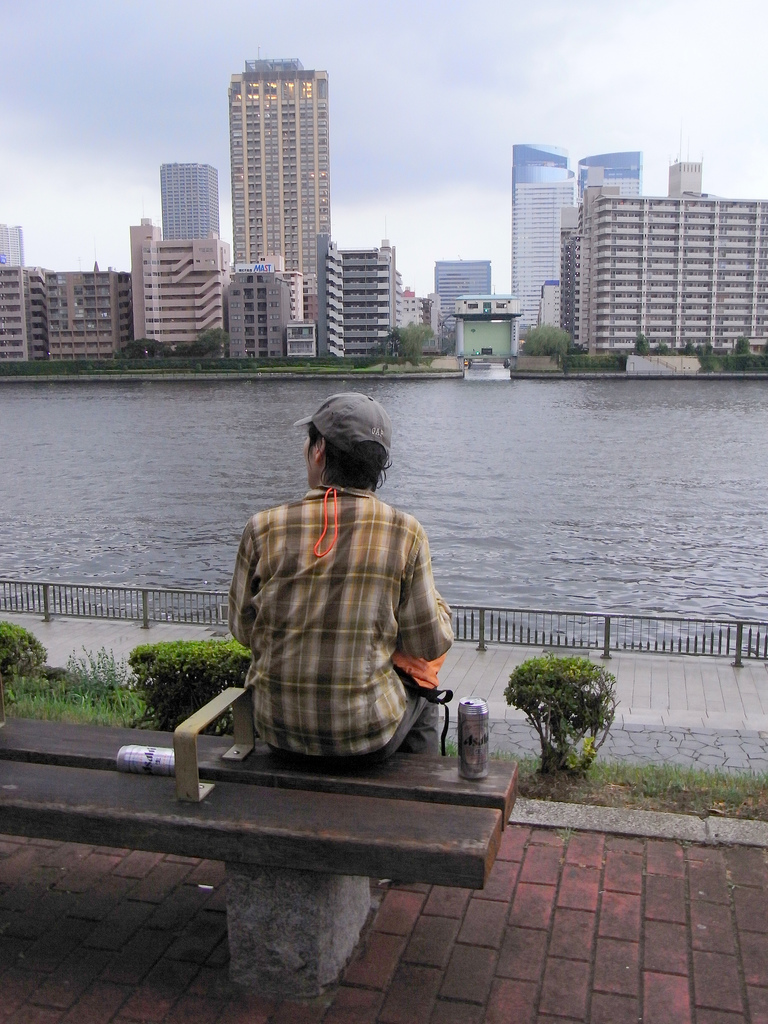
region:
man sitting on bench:
[201, 377, 443, 768]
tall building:
[132, 41, 364, 365]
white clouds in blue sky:
[66, 55, 108, 99]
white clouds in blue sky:
[123, 61, 203, 130]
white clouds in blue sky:
[381, 71, 411, 120]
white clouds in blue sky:
[440, 15, 482, 84]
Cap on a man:
[287, 389, 396, 467]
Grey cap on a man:
[289, 390, 394, 462]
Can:
[453, 692, 493, 784]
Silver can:
[454, 692, 494, 780]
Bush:
[506, 650, 624, 778]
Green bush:
[504, 651, 625, 779]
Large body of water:
[521, 424, 721, 585]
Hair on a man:
[297, 416, 396, 491]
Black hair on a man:
[299, 419, 394, 493]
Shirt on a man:
[227, 487, 454, 757]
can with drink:
[464, 692, 495, 781]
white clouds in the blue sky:
[53, 203, 96, 240]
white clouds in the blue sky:
[350, 106, 407, 147]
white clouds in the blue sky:
[390, 135, 452, 196]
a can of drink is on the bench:
[455, 694, 495, 785]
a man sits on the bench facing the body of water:
[199, 393, 530, 897]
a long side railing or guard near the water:
[8, 572, 767, 668]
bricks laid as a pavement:
[521, 832, 696, 997]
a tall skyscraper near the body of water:
[217, 43, 335, 405]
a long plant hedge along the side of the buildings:
[25, 344, 445, 383]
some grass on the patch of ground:
[534, 753, 763, 839]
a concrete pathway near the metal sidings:
[473, 636, 762, 730]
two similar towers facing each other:
[497, 137, 654, 376]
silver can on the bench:
[452, 693, 492, 787]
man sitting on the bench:
[221, 408, 450, 772]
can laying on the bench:
[110, 736, 183, 779]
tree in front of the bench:
[495, 646, 621, 786]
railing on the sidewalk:
[524, 599, 734, 649]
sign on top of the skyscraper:
[227, 261, 277, 276]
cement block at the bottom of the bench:
[215, 862, 353, 1006]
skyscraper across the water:
[589, 193, 765, 349]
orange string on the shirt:
[303, 490, 355, 563]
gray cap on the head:
[290, 394, 400, 444]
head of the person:
[257, 388, 445, 510]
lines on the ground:
[499, 884, 706, 984]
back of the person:
[177, 452, 462, 753]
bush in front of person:
[492, 630, 652, 787]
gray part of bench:
[138, 843, 408, 1011]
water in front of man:
[523, 415, 721, 553]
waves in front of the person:
[485, 442, 715, 609]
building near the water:
[164, 38, 404, 242]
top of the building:
[176, 38, 385, 130]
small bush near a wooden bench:
[507, 651, 620, 785]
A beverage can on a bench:
[450, 694, 502, 786]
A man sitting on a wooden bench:
[228, 386, 456, 774]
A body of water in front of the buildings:
[3, 375, 766, 655]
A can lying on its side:
[105, 738, 189, 779]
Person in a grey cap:
[225, 384, 448, 764]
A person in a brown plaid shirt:
[230, 384, 442, 770]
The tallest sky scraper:
[223, 52, 330, 354]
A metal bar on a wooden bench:
[163, 674, 258, 794]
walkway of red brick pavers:
[8, 817, 761, 1022]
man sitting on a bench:
[224, 395, 451, 786]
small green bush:
[499, 648, 636, 810]